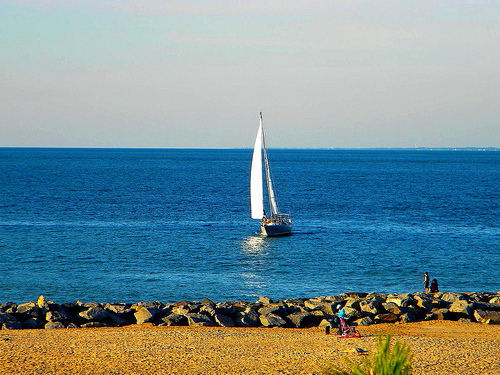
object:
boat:
[250, 110, 293, 236]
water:
[1, 148, 499, 293]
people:
[428, 278, 440, 294]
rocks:
[78, 304, 129, 326]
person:
[336, 304, 345, 334]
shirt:
[338, 309, 345, 317]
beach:
[4, 321, 499, 374]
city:
[229, 146, 500, 153]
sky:
[1, 1, 498, 148]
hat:
[336, 304, 342, 310]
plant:
[308, 334, 411, 375]